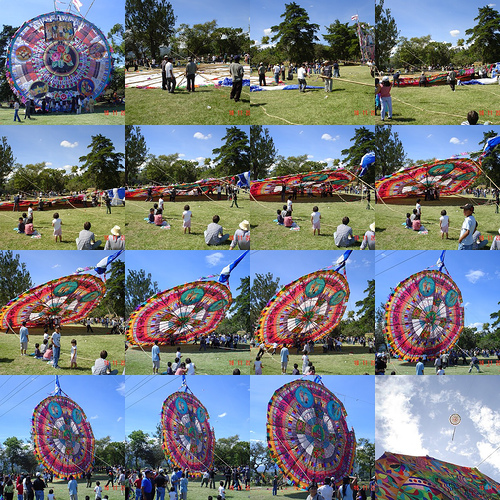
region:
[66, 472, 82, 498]
Person with a blue shirt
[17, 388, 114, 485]
Large multi colored kite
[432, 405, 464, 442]
Small kite in the sky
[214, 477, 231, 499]
Person in a white shirt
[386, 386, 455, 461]
White and blue cloudy sky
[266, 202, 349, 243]
People on green grass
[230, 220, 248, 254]
Person in a tan hat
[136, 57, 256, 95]
Large kite on the ground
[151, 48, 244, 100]
People standing by a kite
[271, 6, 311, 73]
Green trees by a field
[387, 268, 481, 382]
large round multi colored kite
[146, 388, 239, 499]
large round multi colored kite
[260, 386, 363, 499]
large round multi colored kite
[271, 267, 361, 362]
large round multi colored kite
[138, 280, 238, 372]
large round multi colored kite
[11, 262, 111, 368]
large round multi colored kite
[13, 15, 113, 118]
large round multi colored kite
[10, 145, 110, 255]
people sitting on grass watching kite take off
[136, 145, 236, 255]
people sitting on grass watching kite take off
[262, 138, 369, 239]
people sitting on grass watching kite take off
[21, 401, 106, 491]
A giant colorful kite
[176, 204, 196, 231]
A little kid in white top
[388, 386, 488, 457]
Patchy clouds under sun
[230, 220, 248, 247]
An adult person with a white hat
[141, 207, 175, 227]
One adult and one child sitting on a mat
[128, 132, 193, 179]
Some green trees nearby the grassy ground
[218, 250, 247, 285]
A blue and white cloth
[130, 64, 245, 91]
The kite is flat on the ground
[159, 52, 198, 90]
Three men are discussing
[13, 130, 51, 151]
It's a blue sunny sky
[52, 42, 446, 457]
12 pictures are joined together.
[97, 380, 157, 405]
Sky is blue color.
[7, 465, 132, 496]
people are standing in the grass.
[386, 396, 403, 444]
Clouds are white color.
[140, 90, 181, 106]
Grass is green color.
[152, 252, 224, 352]
Big kite is seen.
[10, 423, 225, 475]
Trees are behind the kite.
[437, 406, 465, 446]
One kite is flying in the sky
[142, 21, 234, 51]
trees are green color.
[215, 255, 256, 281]
Blue and white balloon is attached to the kite.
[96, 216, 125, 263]
Person in gray shirt and white hat.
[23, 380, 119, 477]
Large circular kite.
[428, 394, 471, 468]
Kite flying in the sky.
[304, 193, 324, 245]
Toddler in white shirt and shorts.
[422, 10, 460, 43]
Blue sky with a white cloud.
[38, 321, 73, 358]
Person in jeans and white shirt.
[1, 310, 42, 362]
Person in gray shirt and shorts.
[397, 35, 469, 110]
Large kite laying on ground.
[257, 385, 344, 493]
Blue,yellow and white kite.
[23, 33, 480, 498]
Multiple pictures of a kite getting ready to fly.